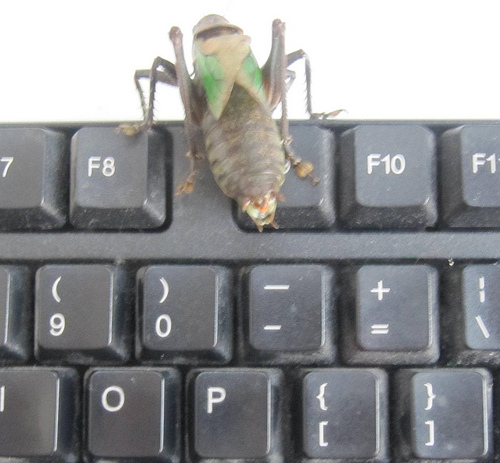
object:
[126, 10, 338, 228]
bug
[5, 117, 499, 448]
keyboard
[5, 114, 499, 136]
edge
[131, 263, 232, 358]
key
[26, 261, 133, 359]
key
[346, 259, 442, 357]
key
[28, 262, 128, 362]
9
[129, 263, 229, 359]
0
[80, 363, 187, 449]
o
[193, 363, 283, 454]
p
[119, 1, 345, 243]
grasshopper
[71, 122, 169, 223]
f8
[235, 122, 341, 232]
f9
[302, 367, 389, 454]
key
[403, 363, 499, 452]
key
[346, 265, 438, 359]
sign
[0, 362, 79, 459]
key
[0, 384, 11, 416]
letter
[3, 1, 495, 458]
photo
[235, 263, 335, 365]
key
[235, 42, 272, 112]
wing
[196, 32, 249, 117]
wing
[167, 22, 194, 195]
leg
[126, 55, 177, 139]
leg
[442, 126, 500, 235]
key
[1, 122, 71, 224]
key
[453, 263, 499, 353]
symbol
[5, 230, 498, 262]
dust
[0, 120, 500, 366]
keys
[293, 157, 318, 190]
foot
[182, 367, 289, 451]
key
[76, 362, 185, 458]
key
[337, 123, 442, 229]
f10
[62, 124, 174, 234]
key